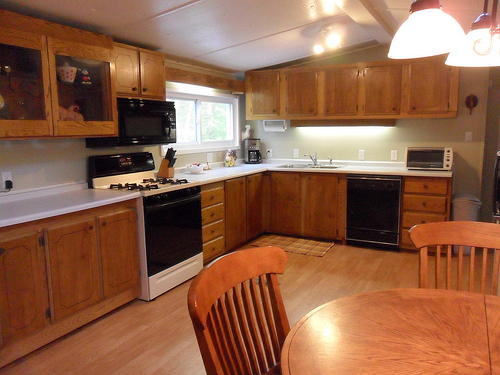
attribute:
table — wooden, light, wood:
[281, 287, 499, 374]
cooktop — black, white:
[89, 169, 201, 197]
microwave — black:
[86, 97, 177, 146]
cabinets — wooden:
[0, 9, 166, 138]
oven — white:
[406, 146, 453, 170]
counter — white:
[2, 150, 453, 230]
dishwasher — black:
[347, 174, 400, 250]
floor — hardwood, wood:
[3, 231, 500, 374]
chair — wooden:
[187, 244, 292, 372]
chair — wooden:
[408, 222, 499, 296]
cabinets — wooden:
[245, 58, 459, 121]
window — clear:
[167, 97, 234, 142]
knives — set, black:
[157, 147, 177, 176]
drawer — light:
[201, 186, 226, 206]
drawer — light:
[201, 202, 225, 227]